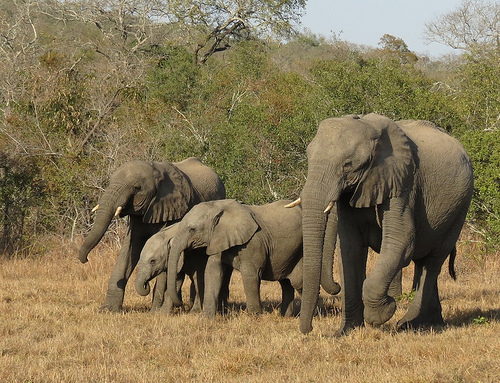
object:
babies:
[131, 182, 320, 323]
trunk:
[129, 264, 160, 300]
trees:
[3, 0, 99, 180]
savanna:
[0, 2, 500, 376]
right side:
[378, 94, 476, 376]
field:
[0, 264, 500, 378]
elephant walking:
[126, 193, 349, 340]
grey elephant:
[77, 153, 233, 331]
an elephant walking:
[165, 192, 325, 322]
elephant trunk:
[278, 146, 360, 340]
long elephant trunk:
[74, 176, 131, 266]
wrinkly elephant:
[164, 182, 325, 322]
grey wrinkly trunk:
[69, 183, 132, 269]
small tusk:
[319, 197, 341, 217]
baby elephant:
[162, 191, 351, 326]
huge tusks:
[65, 170, 138, 234]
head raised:
[76, 161, 164, 270]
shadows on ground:
[94, 267, 500, 353]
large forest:
[0, 0, 500, 265]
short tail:
[439, 225, 472, 291]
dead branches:
[59, 17, 158, 168]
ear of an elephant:
[347, 106, 424, 213]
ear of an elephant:
[195, 204, 259, 267]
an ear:
[140, 160, 193, 225]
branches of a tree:
[176, 0, 306, 76]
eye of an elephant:
[181, 224, 200, 238]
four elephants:
[72, 109, 481, 344]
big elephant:
[282, 108, 488, 340]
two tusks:
[278, 185, 350, 311]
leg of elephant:
[354, 207, 426, 329]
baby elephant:
[130, 207, 267, 321]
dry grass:
[53, 316, 194, 383]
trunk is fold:
[129, 265, 160, 309]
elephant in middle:
[131, 190, 328, 331]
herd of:
[67, 105, 481, 345]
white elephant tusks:
[84, 197, 127, 223]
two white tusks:
[277, 181, 341, 218]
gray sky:
[285, 1, 461, 71]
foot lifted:
[357, 251, 407, 333]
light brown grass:
[0, 307, 500, 382]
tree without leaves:
[93, 39, 149, 100]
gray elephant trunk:
[163, 232, 191, 311]